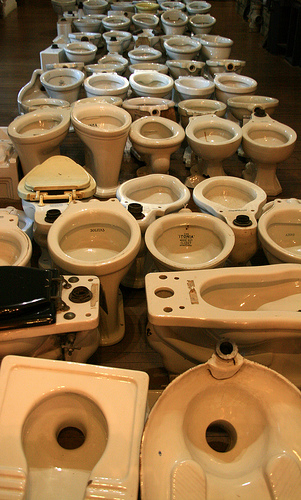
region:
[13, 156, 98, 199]
Triangle shaped toilet seat and lid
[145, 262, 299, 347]
Long and skinny toilet fixture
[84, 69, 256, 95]
Row of white round toilets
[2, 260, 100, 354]
Part of a skinny toilet with a black seat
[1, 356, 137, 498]
Square shaped toilet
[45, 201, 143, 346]
Tall round toilet fixture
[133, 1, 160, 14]
Yellow toilet among white toilets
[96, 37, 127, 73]
Short round toilet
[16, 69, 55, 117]
Toilet laying on its back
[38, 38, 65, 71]
Rectangular toilet tank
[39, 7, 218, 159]
these are the toilet sink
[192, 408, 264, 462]
the hole is small in size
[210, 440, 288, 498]
the sink is white in color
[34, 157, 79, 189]
the lid is closed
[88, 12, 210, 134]
the sink are many in number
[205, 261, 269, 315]
the sink is glass like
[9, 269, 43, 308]
the lid is black in color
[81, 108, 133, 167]
the sink is big in size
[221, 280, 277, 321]
the sink is new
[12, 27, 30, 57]
the floor is wooden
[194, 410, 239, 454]
hole of the toilet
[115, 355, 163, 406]
right angle on object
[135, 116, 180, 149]
white toilet next to other toilets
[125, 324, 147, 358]
ground below the toilets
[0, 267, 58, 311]
black seat of toilet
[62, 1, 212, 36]
toilets in the background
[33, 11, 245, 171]
room with many toilets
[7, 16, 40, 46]
brown floor next to toilets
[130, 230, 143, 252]
edge of the toilet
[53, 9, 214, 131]
toilets in rows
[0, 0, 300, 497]
a large collection of toilets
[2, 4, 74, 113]
hard wood flooring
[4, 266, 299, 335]
a pair of very thin toilets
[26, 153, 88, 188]
a toilet lid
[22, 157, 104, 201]
a toilet seat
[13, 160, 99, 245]
a toilet not missing its lid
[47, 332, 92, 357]
a valve on a toilet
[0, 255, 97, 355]
a thin toilet with a black lid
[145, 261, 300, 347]
a thin toilet with no lid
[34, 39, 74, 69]
the water basin of a toilet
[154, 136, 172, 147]
edge of a tolet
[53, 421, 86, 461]
inside of a toilet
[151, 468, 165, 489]
part of a toilet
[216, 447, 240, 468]
edge of a shade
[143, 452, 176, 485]
part of a toilet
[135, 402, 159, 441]
edge of a toilet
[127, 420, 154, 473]
edge of a toilet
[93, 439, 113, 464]
part of a toilet